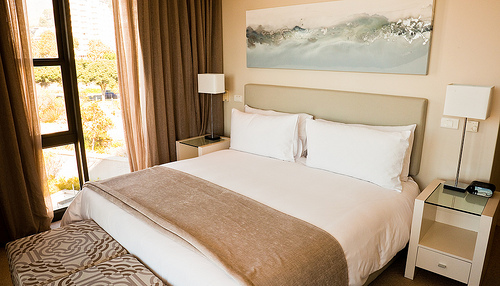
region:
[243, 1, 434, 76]
A painting on a wall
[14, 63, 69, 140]
A window in a room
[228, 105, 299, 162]
White pillow in a room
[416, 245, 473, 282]
Drawer on a nightstand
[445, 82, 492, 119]
A white lampshade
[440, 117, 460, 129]
A light switch on a wall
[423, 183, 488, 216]
Glass top on a nightstand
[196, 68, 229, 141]
Lamp on a corner table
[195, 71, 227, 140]
A lamp sitting on a table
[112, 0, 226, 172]
A brown curtain in a room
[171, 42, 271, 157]
the lamp in a room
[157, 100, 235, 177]
the table in a room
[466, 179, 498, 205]
a clock in a room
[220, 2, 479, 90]
a picture in a room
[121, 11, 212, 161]
a curtain in a room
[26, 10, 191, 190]
a window in a room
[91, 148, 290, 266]
a blanket in a room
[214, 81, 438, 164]
the headboard in a room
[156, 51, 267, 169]
a lamp near a bed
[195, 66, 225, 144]
the lamp on the end table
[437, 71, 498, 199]
the lamp on the table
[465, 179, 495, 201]
the clock on the end table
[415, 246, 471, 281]
the drawer on the end table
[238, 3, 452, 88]
the painting behind the bed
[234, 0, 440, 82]
the picture on the wall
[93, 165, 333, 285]
the blanket on the bed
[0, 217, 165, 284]
the ottoman couch at the end of the bed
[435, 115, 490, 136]
the white switchs on the wall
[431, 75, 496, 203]
bed side lamp with a white square shade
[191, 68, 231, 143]
bed side lamp with a white square shade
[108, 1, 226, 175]
ruffled brown curtain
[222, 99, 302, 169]
rectangular white bed pillow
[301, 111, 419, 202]
rectangular white bed pillow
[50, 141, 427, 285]
fluffy white bed comforter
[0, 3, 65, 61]
rectangular glass window pane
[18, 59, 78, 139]
rectangular glass window pane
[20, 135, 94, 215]
rectangular glass window pane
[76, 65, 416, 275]
bed in the room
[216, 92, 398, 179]
pillows on the bed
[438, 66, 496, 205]
lamp next to bed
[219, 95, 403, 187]
many pillows on bed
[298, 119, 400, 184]
white pillow in photo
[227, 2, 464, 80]
picture above the bed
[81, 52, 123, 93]
trees outside the window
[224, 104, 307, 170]
white pillows on bed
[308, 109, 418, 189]
white pillows on bed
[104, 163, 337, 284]
brown bedspread and white cover on bed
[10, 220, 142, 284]
brown and white seat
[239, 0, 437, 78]
blue and tan painting on wall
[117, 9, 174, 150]
tan window coverings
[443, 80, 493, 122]
white lamp shade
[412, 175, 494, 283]
tan night stand with glass table top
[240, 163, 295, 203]
a comforter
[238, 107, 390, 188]
four pillows on the bed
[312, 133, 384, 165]
a pillow on the bed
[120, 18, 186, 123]
the curtains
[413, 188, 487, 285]
a nightstand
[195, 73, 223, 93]
a lamp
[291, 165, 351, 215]
the comforter is white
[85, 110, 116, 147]
a bush